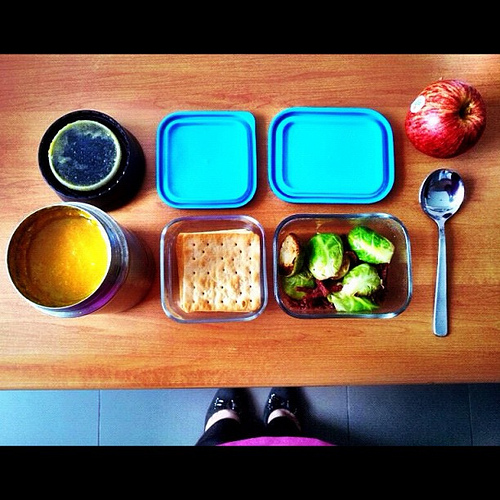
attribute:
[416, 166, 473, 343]
spoon — silver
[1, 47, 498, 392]
table — wooden, brown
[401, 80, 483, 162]
apple — red, round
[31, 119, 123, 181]
lid — black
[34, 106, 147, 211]
lid — black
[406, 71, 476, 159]
apple — mottled, red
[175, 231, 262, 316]
bread — flat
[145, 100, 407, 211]
plastic lids — blue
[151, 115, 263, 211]
lid — blue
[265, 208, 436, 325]
bowl — shaped, rectangle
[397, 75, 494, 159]
apple — red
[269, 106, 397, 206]
lid — rectangular, blue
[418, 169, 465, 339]
spoon — silver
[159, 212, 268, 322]
container — glass, square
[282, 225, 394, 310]
vegetables — green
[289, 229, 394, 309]
salad — leafy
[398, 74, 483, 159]
apple — red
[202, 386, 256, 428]
shoe — black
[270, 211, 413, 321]
container — glass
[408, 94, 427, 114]
sticker — white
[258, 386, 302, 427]
shoe — black